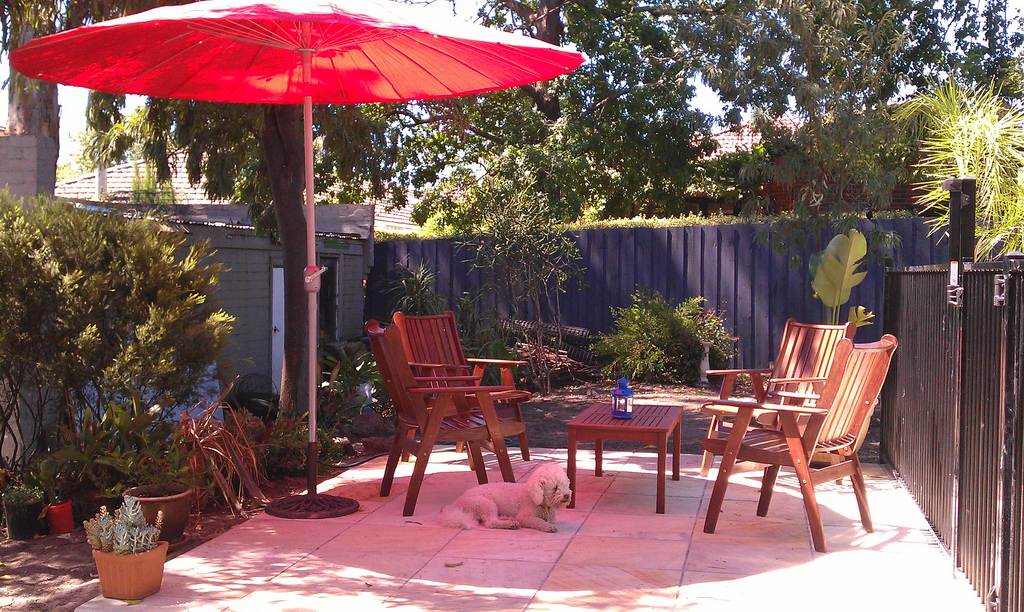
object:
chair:
[365, 309, 535, 518]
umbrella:
[0, 0, 588, 519]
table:
[566, 402, 686, 515]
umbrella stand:
[265, 441, 360, 520]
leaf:
[813, 131, 830, 156]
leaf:
[76, 402, 108, 448]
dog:
[425, 462, 576, 533]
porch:
[269, 443, 663, 612]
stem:
[796, 139, 905, 322]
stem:
[58, 399, 119, 508]